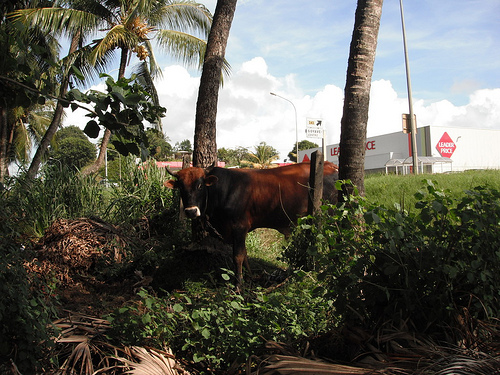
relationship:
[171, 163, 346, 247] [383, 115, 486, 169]
cow near building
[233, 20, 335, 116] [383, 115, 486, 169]
sky above building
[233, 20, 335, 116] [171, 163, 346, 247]
sky above cow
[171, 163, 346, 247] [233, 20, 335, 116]
cow below sky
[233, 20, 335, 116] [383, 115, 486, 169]
sky near building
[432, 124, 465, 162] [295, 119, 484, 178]
sign on side of building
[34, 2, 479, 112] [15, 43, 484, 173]
sky with clouds